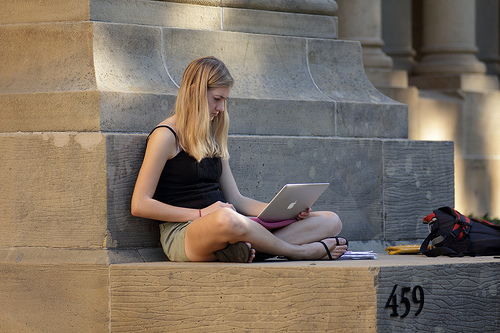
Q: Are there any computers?
A: Yes, there is a computer.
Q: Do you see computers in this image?
A: Yes, there is a computer.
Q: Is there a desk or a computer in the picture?
A: Yes, there is a computer.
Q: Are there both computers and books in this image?
A: No, there is a computer but no books.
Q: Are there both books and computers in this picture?
A: No, there is a computer but no books.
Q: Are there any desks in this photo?
A: No, there are no desks.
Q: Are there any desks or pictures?
A: No, there are no desks or pictures.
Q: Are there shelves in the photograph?
A: No, there are no shelves.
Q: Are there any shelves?
A: No, there are no shelves.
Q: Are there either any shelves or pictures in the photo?
A: No, there are no shelves or pictures.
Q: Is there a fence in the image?
A: No, there are no fences.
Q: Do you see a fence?
A: No, there are no fences.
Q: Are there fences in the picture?
A: No, there are no fences.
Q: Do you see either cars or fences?
A: No, there are no fences or cars.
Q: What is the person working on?
A: The person is working on a computer.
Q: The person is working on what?
A: The person is working on a computer.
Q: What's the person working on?
A: The person is working on a computer.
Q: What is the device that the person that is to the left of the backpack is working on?
A: The device is a computer.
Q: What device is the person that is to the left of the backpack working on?
A: The person is working on a computer.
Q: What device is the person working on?
A: The person is working on a computer.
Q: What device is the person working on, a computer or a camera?
A: The person is working on a computer.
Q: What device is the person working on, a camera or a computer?
A: The person is working on a computer.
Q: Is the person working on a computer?
A: Yes, the person is working on a computer.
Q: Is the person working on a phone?
A: No, the person is working on a computer.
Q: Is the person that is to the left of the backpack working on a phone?
A: No, the person is working on a computer.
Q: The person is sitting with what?
A: The person is sitting with a computer.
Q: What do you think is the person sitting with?
A: The person is sitting with a computer.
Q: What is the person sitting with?
A: The person is sitting with a computer.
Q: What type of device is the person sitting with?
A: The person is sitting with a computer.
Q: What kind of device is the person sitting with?
A: The person is sitting with a computer.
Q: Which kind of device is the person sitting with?
A: The person is sitting with a computer.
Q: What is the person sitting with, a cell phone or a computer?
A: The person is sitting with a computer.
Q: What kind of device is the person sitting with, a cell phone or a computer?
A: The person is sitting with a computer.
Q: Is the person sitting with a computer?
A: Yes, the person is sitting with a computer.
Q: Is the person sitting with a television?
A: No, the person is sitting with a computer.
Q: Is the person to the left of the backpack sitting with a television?
A: No, the person is sitting with a computer.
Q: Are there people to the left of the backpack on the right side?
A: Yes, there is a person to the left of the backpack.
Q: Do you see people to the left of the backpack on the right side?
A: Yes, there is a person to the left of the backpack.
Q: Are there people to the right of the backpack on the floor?
A: No, the person is to the left of the backpack.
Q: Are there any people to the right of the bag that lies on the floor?
A: No, the person is to the left of the backpack.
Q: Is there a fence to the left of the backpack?
A: No, there is a person to the left of the backpack.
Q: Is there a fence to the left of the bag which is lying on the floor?
A: No, there is a person to the left of the backpack.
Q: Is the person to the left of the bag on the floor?
A: Yes, the person is to the left of the backpack.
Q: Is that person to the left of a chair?
A: No, the person is to the left of the backpack.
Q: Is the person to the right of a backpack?
A: No, the person is to the left of a backpack.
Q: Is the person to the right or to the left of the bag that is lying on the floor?
A: The person is to the left of the backpack.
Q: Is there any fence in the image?
A: No, there are no fences.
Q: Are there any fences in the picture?
A: No, there are no fences.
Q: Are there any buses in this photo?
A: No, there are no buses.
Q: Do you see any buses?
A: No, there are no buses.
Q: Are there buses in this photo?
A: No, there are no buses.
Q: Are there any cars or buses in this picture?
A: No, there are no buses or cars.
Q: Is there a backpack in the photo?
A: Yes, there is a backpack.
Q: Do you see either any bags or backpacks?
A: Yes, there is a backpack.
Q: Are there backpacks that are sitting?
A: Yes, there is a backpack that is sitting.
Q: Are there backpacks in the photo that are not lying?
A: Yes, there is a backpack that is sitting.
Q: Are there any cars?
A: No, there are no cars.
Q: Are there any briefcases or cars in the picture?
A: No, there are no cars or briefcases.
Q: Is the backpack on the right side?
A: Yes, the backpack is on the right of the image.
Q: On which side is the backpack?
A: The backpack is on the right of the image.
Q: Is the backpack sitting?
A: Yes, the backpack is sitting.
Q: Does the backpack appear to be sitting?
A: Yes, the backpack is sitting.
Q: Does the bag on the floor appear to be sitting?
A: Yes, the backpack is sitting.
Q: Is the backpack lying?
A: No, the backpack is sitting.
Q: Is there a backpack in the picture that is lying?
A: No, there is a backpack but it is sitting.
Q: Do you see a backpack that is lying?
A: No, there is a backpack but it is sitting.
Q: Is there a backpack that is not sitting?
A: No, there is a backpack but it is sitting.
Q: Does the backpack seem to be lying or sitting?
A: The backpack is sitting.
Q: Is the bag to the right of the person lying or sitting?
A: The backpack is sitting.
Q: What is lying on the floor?
A: The backpack is lying on the floor.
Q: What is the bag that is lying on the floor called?
A: The bag is a backpack.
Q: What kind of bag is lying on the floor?
A: The bag is a backpack.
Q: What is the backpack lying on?
A: The backpack is lying on the floor.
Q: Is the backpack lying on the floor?
A: Yes, the backpack is lying on the floor.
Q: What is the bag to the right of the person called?
A: The bag is a backpack.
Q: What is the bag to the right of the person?
A: The bag is a backpack.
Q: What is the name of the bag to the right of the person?
A: The bag is a backpack.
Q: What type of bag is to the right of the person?
A: The bag is a backpack.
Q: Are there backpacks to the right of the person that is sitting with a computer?
A: Yes, there is a backpack to the right of the person.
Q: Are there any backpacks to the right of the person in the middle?
A: Yes, there is a backpack to the right of the person.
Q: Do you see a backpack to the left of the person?
A: No, the backpack is to the right of the person.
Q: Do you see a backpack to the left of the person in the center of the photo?
A: No, the backpack is to the right of the person.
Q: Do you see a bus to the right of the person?
A: No, there is a backpack to the right of the person.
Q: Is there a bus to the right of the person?
A: No, there is a backpack to the right of the person.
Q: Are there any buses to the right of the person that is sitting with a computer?
A: No, there is a backpack to the right of the person.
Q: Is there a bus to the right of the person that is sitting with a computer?
A: No, there is a backpack to the right of the person.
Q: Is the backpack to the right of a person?
A: Yes, the backpack is to the right of a person.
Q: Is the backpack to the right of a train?
A: No, the backpack is to the right of a person.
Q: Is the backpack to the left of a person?
A: No, the backpack is to the right of a person.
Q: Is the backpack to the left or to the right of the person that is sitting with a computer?
A: The backpack is to the right of the person.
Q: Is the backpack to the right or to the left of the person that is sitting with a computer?
A: The backpack is to the right of the person.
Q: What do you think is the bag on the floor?
A: The bag is a backpack.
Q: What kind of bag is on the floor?
A: The bag is a backpack.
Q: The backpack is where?
A: The backpack is on the floor.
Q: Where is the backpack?
A: The backpack is on the floor.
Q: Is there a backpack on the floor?
A: Yes, there is a backpack on the floor.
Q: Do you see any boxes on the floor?
A: No, there is a backpack on the floor.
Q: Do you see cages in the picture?
A: No, there are no cages.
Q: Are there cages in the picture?
A: No, there are no cages.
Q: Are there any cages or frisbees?
A: No, there are no cages or frisbees.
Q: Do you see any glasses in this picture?
A: No, there are no glasses.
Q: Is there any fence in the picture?
A: No, there are no fences.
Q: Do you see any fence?
A: No, there are no fences.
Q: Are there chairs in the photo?
A: No, there are no chairs.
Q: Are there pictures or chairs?
A: No, there are no chairs or pictures.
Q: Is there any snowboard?
A: No, there are no snowboards.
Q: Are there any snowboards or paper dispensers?
A: No, there are no snowboards or paper dispensers.